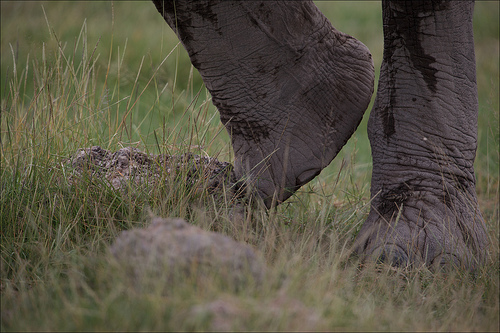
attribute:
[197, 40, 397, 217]
foot — touching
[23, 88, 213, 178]
grass — tall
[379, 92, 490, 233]
foot — wrinkled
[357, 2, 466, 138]
leg — dark, marked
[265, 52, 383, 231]
foot — flat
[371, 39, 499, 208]
fold — slanted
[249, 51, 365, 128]
wrinkles — vertical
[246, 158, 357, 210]
foot — oval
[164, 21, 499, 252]
feet — gray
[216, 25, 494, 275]
feet — wrinkled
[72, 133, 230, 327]
rocks — grey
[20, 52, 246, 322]
grass — yellow, stringy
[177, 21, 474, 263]
foot — raised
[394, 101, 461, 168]
leg — white, spotted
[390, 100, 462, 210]
skin — gray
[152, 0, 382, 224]
leg — raised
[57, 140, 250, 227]
mound — dirt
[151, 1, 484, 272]
elephant — big feet, grey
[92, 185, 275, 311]
mounds — dirt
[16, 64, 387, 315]
fields — grass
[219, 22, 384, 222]
feet — gray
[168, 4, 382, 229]
skin — rough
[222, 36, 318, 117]
skin — gray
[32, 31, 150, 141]
grass — yellow, green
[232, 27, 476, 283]
feet — elephant', dirty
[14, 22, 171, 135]
grass — green ,  elephant's feet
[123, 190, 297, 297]
dirt — pile 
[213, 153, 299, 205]
nails — elephants ,  dirty.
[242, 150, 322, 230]
nails —  dirty., elephants 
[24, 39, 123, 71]
grass — green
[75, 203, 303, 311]
dirt — brown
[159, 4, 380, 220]
feet — large